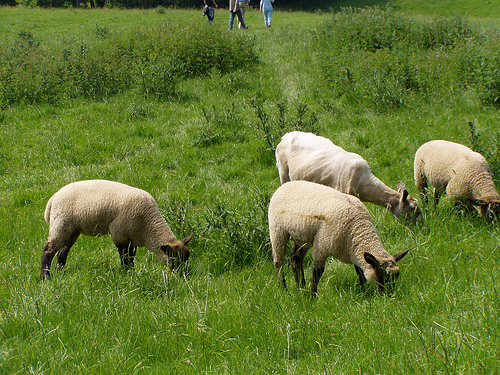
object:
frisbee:
[246, 3, 250, 6]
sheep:
[275, 131, 428, 236]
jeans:
[262, 5, 273, 26]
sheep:
[268, 179, 412, 299]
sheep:
[39, 179, 195, 281]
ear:
[402, 189, 409, 203]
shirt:
[204, 0, 215, 7]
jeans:
[228, 11, 249, 31]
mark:
[279, 210, 326, 223]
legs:
[271, 245, 333, 292]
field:
[0, 0, 500, 375]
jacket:
[202, 5, 215, 21]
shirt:
[228, 0, 243, 12]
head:
[363, 248, 411, 295]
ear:
[363, 252, 381, 272]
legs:
[41, 237, 137, 280]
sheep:
[413, 139, 500, 228]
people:
[201, 0, 274, 30]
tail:
[44, 195, 53, 223]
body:
[268, 180, 364, 261]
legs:
[228, 11, 247, 29]